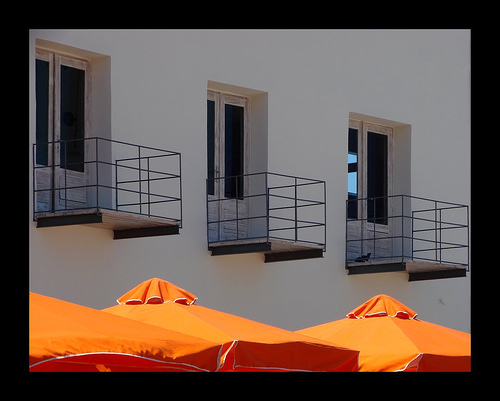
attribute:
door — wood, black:
[344, 114, 395, 264]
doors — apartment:
[36, 40, 96, 206]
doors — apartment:
[205, 89, 252, 239]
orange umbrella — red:
[102, 271, 362, 381]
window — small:
[349, 129, 356, 219]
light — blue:
[347, 150, 357, 192]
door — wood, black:
[204, 85, 247, 245]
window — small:
[345, 127, 357, 219]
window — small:
[225, 102, 243, 197]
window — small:
[207, 100, 214, 194]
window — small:
[366, 130, 387, 224]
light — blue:
[348, 152, 356, 193]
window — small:
[33, 51, 90, 175]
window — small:
[322, 89, 436, 284]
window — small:
[346, 118, 396, 235]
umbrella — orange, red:
[27, 277, 471, 373]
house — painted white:
[38, 36, 476, 365]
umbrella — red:
[30, 269, 223, 369]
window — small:
[341, 153, 357, 194]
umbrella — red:
[74, 274, 377, 374]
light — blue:
[348, 154, 355, 192]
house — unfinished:
[32, 27, 457, 339]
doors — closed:
[35, 52, 102, 208]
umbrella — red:
[105, 275, 200, 305]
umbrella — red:
[344, 293, 420, 318]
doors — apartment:
[28, 45, 93, 213]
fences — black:
[45, 127, 197, 244]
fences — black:
[200, 166, 326, 252]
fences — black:
[341, 192, 463, 267]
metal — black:
[34, 138, 444, 279]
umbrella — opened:
[297, 293, 472, 370]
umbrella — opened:
[100, 270, 362, 367]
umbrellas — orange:
[276, 292, 479, 395]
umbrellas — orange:
[117, 274, 359, 399]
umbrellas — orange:
[28, 268, 183, 391]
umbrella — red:
[121, 272, 191, 302]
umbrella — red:
[69, 216, 463, 368]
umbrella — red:
[290, 291, 469, 368]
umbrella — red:
[93, 276, 355, 371]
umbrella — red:
[25, 291, 220, 370]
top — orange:
[106, 269, 196, 307]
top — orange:
[113, 270, 198, 309]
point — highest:
[340, 283, 419, 324]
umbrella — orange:
[276, 297, 480, 382]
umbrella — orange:
[100, 275, 286, 365]